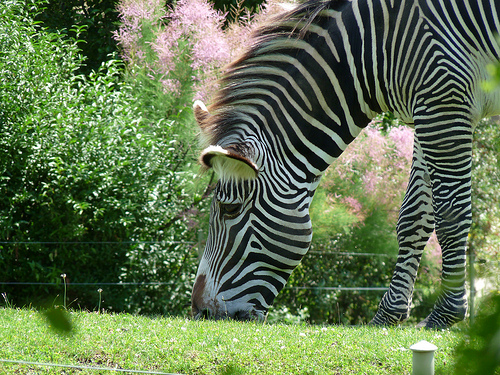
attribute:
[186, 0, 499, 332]
zebra — white, black, striped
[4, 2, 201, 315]
bush — green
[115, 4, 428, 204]
flower — pink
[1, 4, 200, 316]
leaves — purple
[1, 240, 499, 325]
fence — meshed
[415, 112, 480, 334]
leg — white, black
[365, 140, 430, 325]
leg — black, white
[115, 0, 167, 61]
flowers — pink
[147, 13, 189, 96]
flowers — pink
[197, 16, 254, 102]
flowers — pink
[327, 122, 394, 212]
flowers — pink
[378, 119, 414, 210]
flowers — pink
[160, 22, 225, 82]
flower — fuzzy, pink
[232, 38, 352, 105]
fur — black, white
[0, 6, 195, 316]
vegetation — thick, green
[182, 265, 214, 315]
nose — brown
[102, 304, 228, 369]
grass — green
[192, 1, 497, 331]
fur — white, black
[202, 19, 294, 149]
mane — brown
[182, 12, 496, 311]
fur — white, black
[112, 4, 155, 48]
flower — pink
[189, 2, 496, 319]
stripes — white, black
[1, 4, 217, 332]
bush — green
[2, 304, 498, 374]
field — grassy